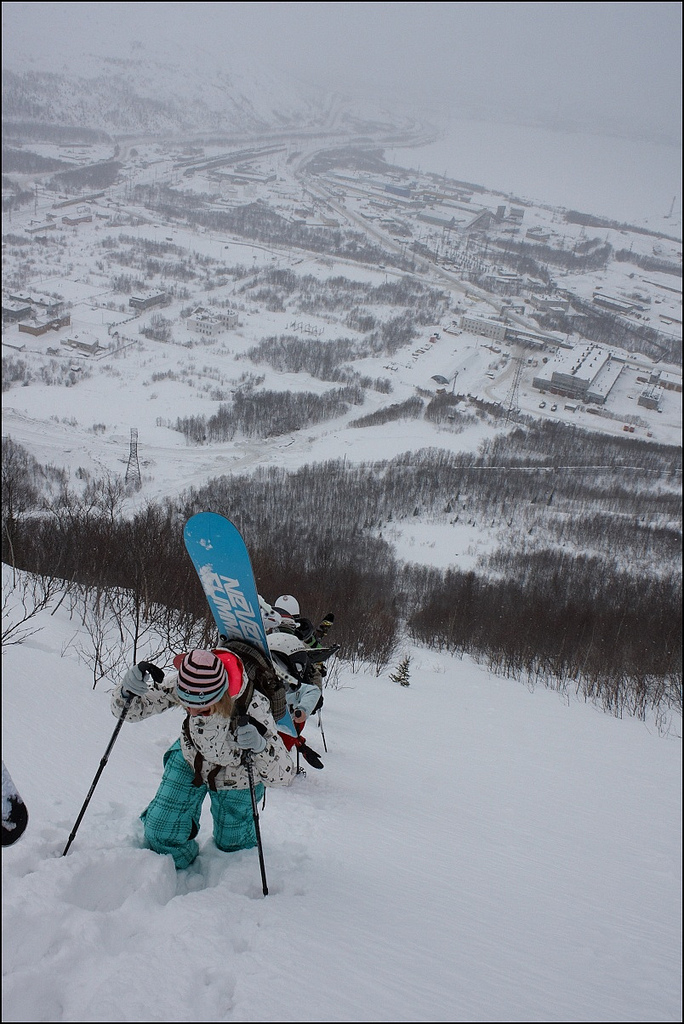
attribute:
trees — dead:
[74, 517, 396, 638]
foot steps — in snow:
[21, 845, 177, 1017]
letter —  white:
[213, 578, 242, 602]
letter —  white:
[218, 578, 245, 595]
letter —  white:
[216, 570, 245, 597]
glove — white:
[232, 718, 269, 762]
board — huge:
[178, 509, 293, 715]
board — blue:
[181, 509, 280, 696]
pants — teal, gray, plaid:
[138, 733, 264, 873]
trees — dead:
[439, 570, 598, 643]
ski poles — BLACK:
[60, 685, 278, 883]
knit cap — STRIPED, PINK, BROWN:
[161, 645, 233, 704]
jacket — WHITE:
[118, 671, 295, 789]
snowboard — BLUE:
[170, 507, 284, 652]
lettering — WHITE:
[195, 565, 269, 643]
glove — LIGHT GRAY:
[110, 651, 157, 711]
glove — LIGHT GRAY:
[226, 722, 273, 759]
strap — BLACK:
[136, 656, 172, 695]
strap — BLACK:
[226, 707, 275, 736]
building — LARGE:
[530, 343, 633, 410]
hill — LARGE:
[50, 611, 681, 987]